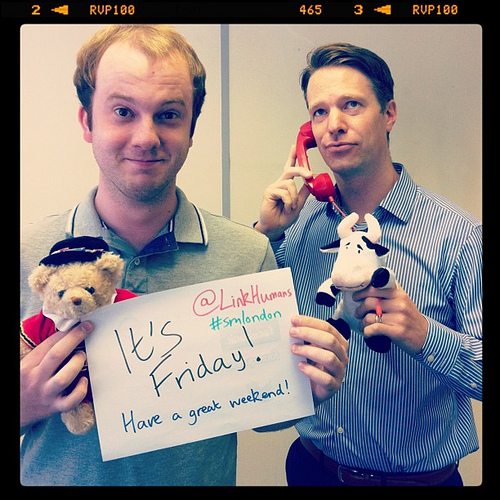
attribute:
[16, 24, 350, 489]
man — posing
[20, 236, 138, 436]
bear — stuffed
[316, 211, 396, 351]
cow — black, white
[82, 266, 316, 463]
sign — held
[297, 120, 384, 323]
phone — red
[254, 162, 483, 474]
shirt — striped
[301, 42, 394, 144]
hair — brown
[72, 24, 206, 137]
hair — blonde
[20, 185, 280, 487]
polo — gray